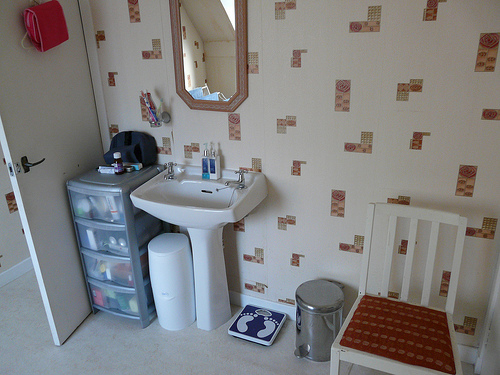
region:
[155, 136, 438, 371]
this is a bathroom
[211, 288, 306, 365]
this is a scale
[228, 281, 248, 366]
the scale is blue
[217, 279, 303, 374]
the scale has footprints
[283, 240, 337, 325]
this is a trashcan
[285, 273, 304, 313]
the can is silver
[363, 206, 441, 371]
this is a chair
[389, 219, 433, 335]
the chair is white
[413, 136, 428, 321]
the chair is wooden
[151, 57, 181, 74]
this is a mirror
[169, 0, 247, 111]
the mirror on the wall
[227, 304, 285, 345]
the scale near the sink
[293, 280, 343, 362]
the silver trash can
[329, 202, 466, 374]
the empty chair against the wall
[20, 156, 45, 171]
the handle on the door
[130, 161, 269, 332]
the white bathroom sink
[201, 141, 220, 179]
the pump bottles on the sink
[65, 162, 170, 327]
the plastic container next to the sink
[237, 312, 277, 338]
the footprints on the scale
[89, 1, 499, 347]
the wall paper on the wall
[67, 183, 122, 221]
a large square plastic drawer of a storage unit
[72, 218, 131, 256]
a large square plastic drawer of a storage unit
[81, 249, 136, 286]
a large square plastic drawer of a storage unit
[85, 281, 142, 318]
a large square plastic drawer of a storage unit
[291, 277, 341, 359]
a small metal trash can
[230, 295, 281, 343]
a blue and white scale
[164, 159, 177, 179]
a silver faucet of a sink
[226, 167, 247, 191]
a silver faucet of a sink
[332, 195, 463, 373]
a red and white chair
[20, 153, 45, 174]
a metal door handle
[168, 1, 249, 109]
A mirror hanging on the wall.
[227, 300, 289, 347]
A weighing scale on the ground.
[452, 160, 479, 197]
A pattern on the wall.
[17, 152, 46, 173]
A handle on a door.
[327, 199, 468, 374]
A empty white chair with pattern seat.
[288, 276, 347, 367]
A small garbage can.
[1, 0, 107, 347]
A white open door.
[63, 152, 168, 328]
A container full of items.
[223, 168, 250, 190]
The knob on a sink.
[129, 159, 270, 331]
A all white sink.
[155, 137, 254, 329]
white sink in bathroom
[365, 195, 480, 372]
white chair with red cushion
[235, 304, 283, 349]
blue and white scale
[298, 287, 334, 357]
silver trash can in bathroom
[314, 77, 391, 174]
small designs on white wall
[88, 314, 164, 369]
white tile floor of bathroom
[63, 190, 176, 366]
gray plastic cabinet on left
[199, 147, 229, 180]
small soaps on sink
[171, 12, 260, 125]
mirror on bathroom wall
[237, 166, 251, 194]
silver faucet on sink